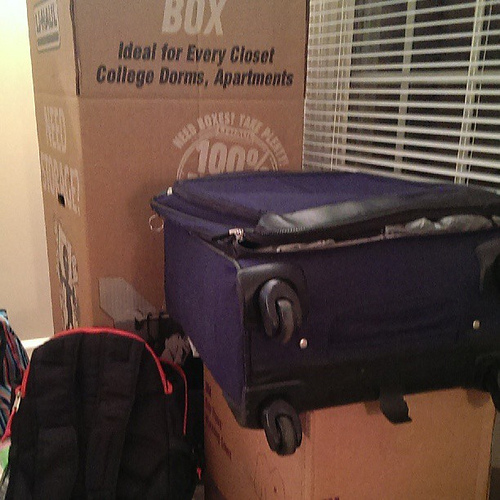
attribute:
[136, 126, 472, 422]
suitcase — blue, open, multicolored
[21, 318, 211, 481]
backpack — black, sitting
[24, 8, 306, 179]
box — brown, big, sitting, large, printing, cardboard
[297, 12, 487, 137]
blind — white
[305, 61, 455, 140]
window — covered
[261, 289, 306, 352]
wheel — black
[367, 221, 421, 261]
zipper — teeth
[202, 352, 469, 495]
bottom — suitcase